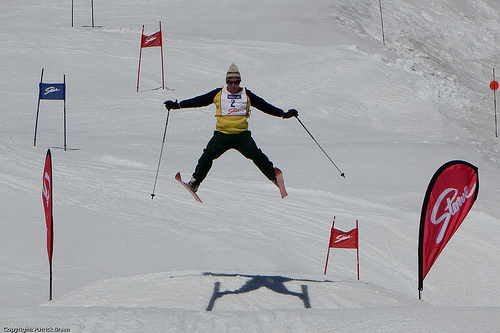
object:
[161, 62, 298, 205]
man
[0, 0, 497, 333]
air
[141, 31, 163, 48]
flag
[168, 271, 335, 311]
shadow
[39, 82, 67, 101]
flag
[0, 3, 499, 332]
snow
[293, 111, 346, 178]
ski pole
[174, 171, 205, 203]
skis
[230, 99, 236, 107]
number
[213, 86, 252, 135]
shirt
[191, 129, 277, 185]
pants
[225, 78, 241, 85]
sunglasses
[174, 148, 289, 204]
spread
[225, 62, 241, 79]
cap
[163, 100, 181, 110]
glove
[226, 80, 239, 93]
face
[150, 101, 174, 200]
poles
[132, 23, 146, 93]
poles